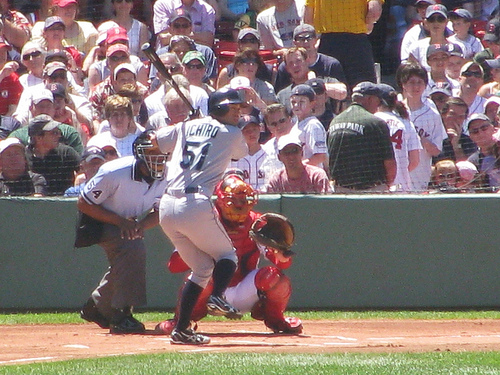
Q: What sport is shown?
A: Baseball.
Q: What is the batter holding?
A: Baseball bat.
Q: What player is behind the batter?
A: Catcher.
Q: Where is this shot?
A: Ball game.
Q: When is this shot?
A: Daytime.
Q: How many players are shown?
A: 2.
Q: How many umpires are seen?
A: 1.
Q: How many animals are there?
A: 0.